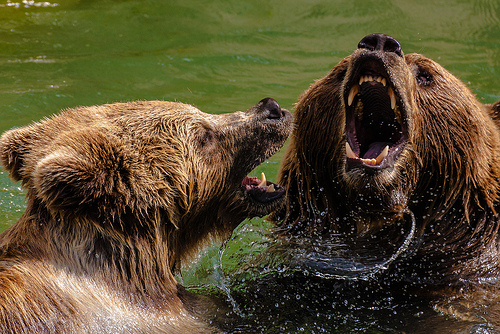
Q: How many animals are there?
A: Two.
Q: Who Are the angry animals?
A: Bears.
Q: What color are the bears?
A: Brown.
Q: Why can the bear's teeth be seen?
A: The bear has its mouth open.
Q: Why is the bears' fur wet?
A: The bears are in water.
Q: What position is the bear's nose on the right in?
A: Pointing up in the air.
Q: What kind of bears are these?
A: Grizzly.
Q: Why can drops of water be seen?
A: It is dripping off the bears.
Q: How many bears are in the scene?
A: Two.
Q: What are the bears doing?
A: Playing.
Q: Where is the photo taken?
A: In the water.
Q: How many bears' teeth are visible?
A: Two.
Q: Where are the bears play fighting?
A: Water.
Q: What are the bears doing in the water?
A: Play fighting.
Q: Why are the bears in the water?
A: Play fighting.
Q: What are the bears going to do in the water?
A: Play fight.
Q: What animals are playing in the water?
A: Bears.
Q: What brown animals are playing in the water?
A: Bears.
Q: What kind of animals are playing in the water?
A: Bears.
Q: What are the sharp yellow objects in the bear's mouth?
A: Teeth.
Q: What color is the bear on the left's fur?
A: Brown.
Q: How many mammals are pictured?
A: Two.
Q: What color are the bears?
A: Brown.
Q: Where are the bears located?
A: In water.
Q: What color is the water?
A: Green.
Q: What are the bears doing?
A: Playing with each other.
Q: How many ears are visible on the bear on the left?
A: Two.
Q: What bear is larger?
A: The one on the right.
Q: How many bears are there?
A: Two.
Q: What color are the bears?
A: Brown.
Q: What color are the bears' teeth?
A: White.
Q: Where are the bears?
A: In the water.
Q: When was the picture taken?
A: Daytime.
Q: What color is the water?
A: Green.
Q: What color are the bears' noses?
A: Black.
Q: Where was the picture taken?
A: In a lake.